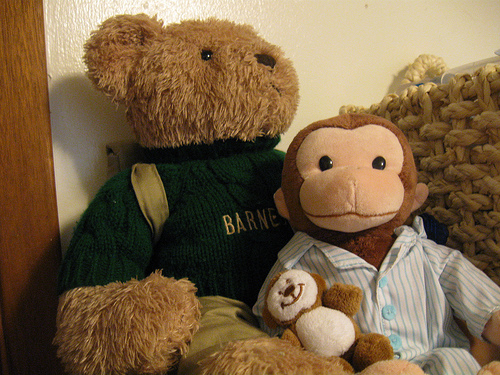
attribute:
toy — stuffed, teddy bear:
[159, 77, 201, 128]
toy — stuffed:
[294, 151, 403, 287]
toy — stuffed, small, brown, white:
[282, 288, 348, 349]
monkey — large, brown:
[302, 130, 443, 338]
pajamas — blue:
[397, 278, 439, 336]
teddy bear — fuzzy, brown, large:
[108, 37, 281, 242]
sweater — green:
[172, 169, 244, 220]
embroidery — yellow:
[241, 213, 274, 227]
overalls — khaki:
[146, 186, 161, 206]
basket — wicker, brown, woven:
[446, 105, 498, 210]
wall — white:
[301, 5, 446, 54]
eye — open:
[198, 43, 222, 63]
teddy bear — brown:
[271, 276, 332, 348]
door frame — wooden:
[7, 40, 56, 199]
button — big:
[381, 307, 397, 319]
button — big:
[382, 281, 390, 288]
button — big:
[394, 337, 401, 343]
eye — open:
[321, 159, 333, 168]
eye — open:
[376, 156, 386, 168]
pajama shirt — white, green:
[358, 280, 454, 325]